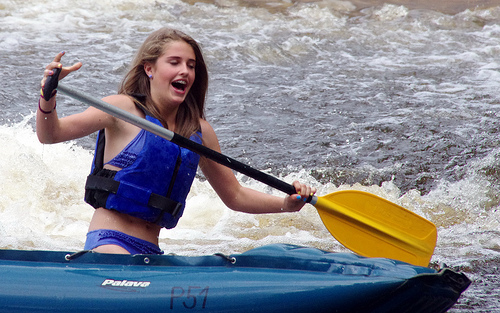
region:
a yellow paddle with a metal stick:
[43, 69, 438, 263]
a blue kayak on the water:
[2, 244, 469, 307]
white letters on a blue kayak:
[101, 274, 149, 289]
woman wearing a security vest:
[86, 90, 201, 228]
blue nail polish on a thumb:
[296, 194, 302, 201]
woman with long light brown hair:
[121, 26, 208, 145]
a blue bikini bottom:
[83, 232, 163, 254]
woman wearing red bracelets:
[34, 88, 57, 115]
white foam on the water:
[0, 121, 499, 266]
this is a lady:
[35, 19, 265, 264]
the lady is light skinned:
[69, 113, 94, 128]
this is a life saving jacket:
[122, 146, 226, 225]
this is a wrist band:
[41, 100, 57, 115]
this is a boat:
[229, 242, 379, 301]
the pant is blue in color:
[120, 236, 143, 251]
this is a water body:
[279, 42, 458, 148]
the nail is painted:
[293, 190, 306, 206]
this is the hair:
[133, 45, 146, 69]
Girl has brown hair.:
[122, 23, 218, 84]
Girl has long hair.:
[103, 30, 225, 147]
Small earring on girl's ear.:
[141, 73, 160, 82]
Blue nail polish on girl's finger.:
[291, 189, 306, 211]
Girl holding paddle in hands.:
[19, 63, 94, 108]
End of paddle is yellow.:
[322, 193, 420, 230]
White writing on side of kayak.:
[98, 270, 181, 280]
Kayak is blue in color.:
[166, 265, 337, 274]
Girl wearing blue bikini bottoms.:
[91, 226, 167, 251]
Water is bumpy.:
[257, 38, 427, 118]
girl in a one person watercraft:
[1, 26, 471, 311]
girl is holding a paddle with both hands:
[36, 50, 436, 265]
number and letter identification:
[165, 280, 207, 310]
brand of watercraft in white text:
[100, 275, 150, 285]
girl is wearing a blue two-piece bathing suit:
[85, 105, 175, 255]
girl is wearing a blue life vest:
[82, 101, 197, 226]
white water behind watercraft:
[1, 107, 496, 304]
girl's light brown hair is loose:
[121, 25, 208, 140]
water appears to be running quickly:
[3, 1, 499, 182]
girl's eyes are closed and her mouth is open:
[165, 52, 196, 99]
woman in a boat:
[1, 28, 470, 310]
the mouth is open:
[171, 77, 185, 89]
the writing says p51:
[170, 283, 207, 308]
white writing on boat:
[102, 280, 149, 286]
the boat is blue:
[0, 249, 470, 311]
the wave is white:
[2, 117, 498, 263]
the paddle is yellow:
[314, 190, 439, 266]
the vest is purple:
[86, 107, 203, 229]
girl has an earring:
[147, 70, 153, 75]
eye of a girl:
[168, 58, 180, 66]